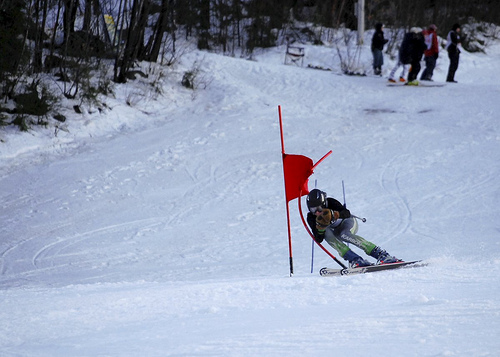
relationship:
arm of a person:
[306, 212, 327, 242] [326, 193, 358, 218]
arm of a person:
[325, 199, 351, 223] [304, 183, 404, 269]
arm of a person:
[306, 212, 323, 242] [304, 183, 404, 269]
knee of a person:
[320, 226, 356, 241] [304, 183, 404, 269]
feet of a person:
[348, 255, 404, 266] [304, 183, 404, 269]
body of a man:
[302, 202, 396, 266] [306, 188, 404, 270]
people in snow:
[367, 16, 482, 98] [198, 41, 497, 263]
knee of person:
[338, 213, 370, 266] [286, 183, 402, 271]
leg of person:
[324, 231, 405, 268] [301, 187, 421, 278]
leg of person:
[345, 220, 374, 267] [292, 180, 426, 280]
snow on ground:
[5, 42, 496, 354] [141, 274, 378, 339]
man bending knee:
[306, 187, 406, 265] [336, 228, 352, 241]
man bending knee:
[306, 187, 406, 265] [325, 228, 334, 243]